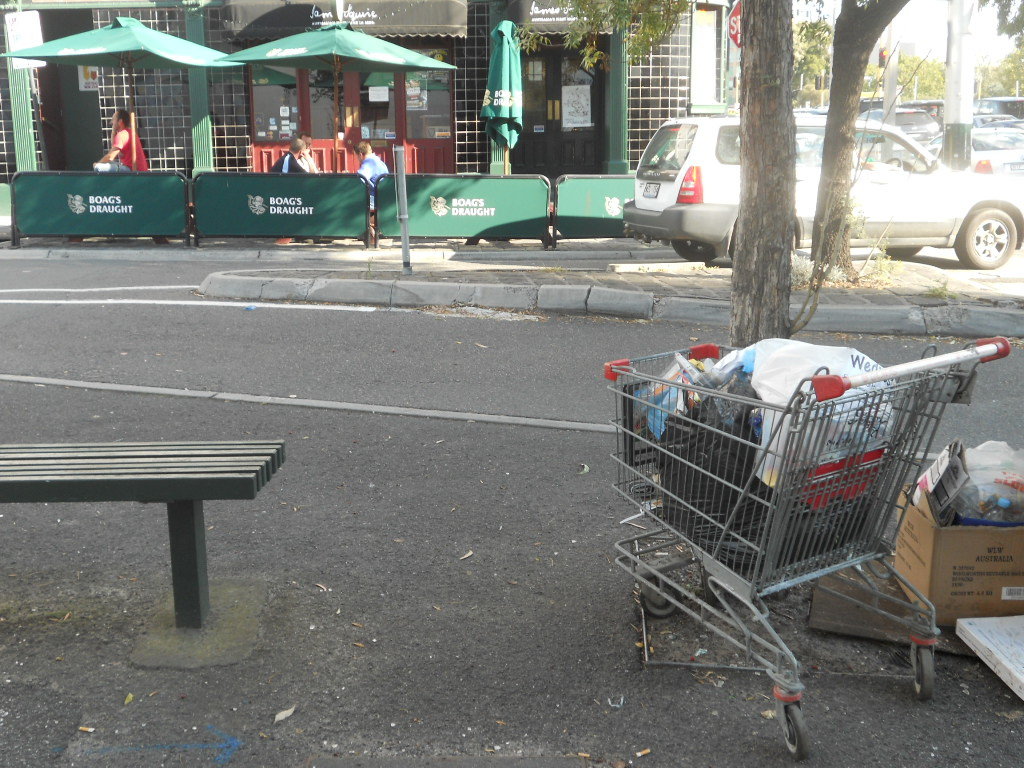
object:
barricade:
[11, 158, 191, 252]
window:
[647, 67, 693, 97]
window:
[621, 32, 687, 91]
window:
[397, 68, 456, 144]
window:
[454, 51, 481, 89]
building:
[0, 0, 731, 248]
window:
[304, 65, 347, 140]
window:
[134, 102, 189, 132]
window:
[154, 69, 192, 111]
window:
[151, 92, 187, 140]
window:
[238, 69, 268, 95]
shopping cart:
[603, 329, 1018, 756]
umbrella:
[209, 20, 459, 89]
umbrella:
[0, 9, 220, 73]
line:
[0, 370, 615, 438]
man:
[94, 109, 155, 170]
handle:
[783, 334, 1021, 400]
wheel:
[954, 207, 1024, 269]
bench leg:
[151, 501, 226, 637]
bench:
[0, 430, 290, 629]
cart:
[586, 308, 1023, 765]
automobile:
[614, 107, 1023, 275]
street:
[0, 298, 1018, 759]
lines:
[0, 286, 388, 320]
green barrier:
[6, 150, 639, 250]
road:
[0, 296, 1021, 740]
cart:
[570, 302, 1022, 765]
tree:
[723, 0, 803, 350]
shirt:
[102, 128, 151, 172]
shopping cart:
[595, 332, 1011, 704]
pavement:
[0, 300, 992, 740]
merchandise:
[649, 332, 899, 518]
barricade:
[183, 163, 381, 256]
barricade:
[373, 168, 554, 251]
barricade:
[555, 168, 636, 242]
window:
[95, 12, 193, 175]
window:
[206, 70, 254, 173]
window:
[388, 40, 483, 174]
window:
[632, 4, 697, 177]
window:
[245, 66, 304, 145]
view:
[0, 346, 691, 480]